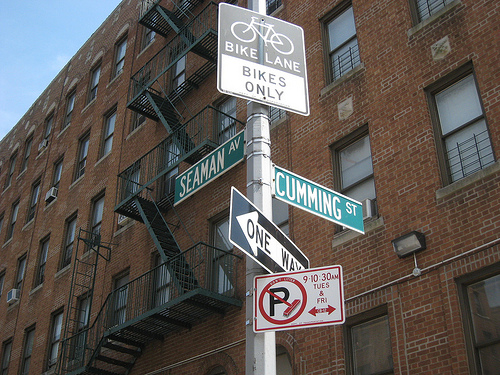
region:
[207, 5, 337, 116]
BIKE LANE SIGN IN PHOTO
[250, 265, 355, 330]
NO PARKING SIGN IN PICTURE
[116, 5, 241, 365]
FIRE ESCAPE IN PHOTO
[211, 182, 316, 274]
A ONE WAY SIGN IN THE PICTURE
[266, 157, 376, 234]
CUMMING ST SIGN IN THE PICTURE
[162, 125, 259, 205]
SEAMAN AV SIGN IN THE PHOTO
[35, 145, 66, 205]
AN AIR CONDITIONER IN A WINDOW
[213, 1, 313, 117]
A BIKES ONLY SIGN IN PHOTO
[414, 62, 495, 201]
A BUILDING WINDOW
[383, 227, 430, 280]
A LIGHT IN THE PHOTO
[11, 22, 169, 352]
brick buildings with windows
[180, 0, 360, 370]
pole with street signs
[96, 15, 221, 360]
fire escape on buildings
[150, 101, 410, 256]
street signs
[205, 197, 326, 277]
one way street sign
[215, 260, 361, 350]
street cleaning sign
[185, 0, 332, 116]
sign for the bike lane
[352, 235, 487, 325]
lights for building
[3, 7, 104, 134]
blue sky over building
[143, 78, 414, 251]
corner of seaman ave and cumming st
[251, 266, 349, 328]
No Parking sign on pole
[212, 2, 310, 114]
Bike lane sign on pole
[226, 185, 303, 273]
One way sign on pole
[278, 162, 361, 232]
Street sign says Cumming St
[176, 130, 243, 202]
Street sign says Seaman Av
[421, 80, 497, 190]
Window with safety bars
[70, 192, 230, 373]
fire escape on side of building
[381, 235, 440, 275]
light on side of building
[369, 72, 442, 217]
Building exterior is brick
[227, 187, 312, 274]
One way sign is black and white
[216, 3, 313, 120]
There is a sign for bikes only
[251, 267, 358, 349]
The sign says no parking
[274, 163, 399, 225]
The sign says cumming st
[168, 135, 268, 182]
The sign says seaman av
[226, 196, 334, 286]
The sign says one way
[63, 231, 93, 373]
There is a black ladder on the building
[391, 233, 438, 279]
There is a light on the building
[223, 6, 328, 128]
There is a bike on the sign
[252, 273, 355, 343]
The sign is red and white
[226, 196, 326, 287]
The sign with the arrow is black and white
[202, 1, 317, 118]
bike lane sign saying bikes only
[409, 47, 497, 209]
apartment building window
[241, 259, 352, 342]
Parking sign, no parking Tuesday and Friday from 9 to 10:30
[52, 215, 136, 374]
fire escape ladder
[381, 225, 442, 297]
apartment building light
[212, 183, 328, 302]
One Way traffic sign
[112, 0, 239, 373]
apartment building fire escape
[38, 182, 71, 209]
window air conditioning unit in apartment building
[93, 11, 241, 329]
fire escape of an apartment building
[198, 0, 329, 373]
sign post with five signs posted